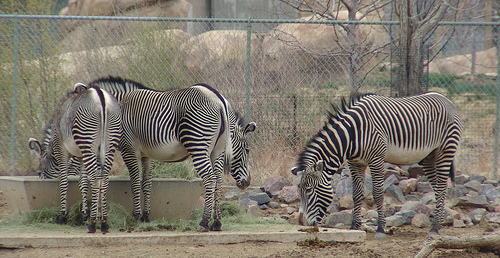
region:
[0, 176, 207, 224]
a trough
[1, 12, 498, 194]
a chain link fence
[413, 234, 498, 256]
a branch off to the side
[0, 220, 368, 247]
a slab of concrete being used as a ground surface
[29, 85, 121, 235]
a zebra eating from a trough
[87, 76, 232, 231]
a zebra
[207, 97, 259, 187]
a zebra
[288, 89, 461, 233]
a zebra eating something off of the ground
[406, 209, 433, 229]
a pinkish rock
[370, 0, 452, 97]
a tree behind the chain link fence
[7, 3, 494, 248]
animals in a zoo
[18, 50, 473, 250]
zebras in front of a fence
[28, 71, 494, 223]
three zebras eating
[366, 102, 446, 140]
zebra stripes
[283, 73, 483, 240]
one zebra eating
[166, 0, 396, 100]
rocks behind a fence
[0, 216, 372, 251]
slab of concrete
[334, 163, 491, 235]
large pile of rocks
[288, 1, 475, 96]
one tree behind a fence, one tree in front of a fence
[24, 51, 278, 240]
three zebras eating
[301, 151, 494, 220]
A pile of rocks behind a zebra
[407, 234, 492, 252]
A log on the ground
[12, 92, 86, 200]
A zebra drinks from a trough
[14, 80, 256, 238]
Three zebras stand together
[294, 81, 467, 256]
One zebra stands alone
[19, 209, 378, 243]
A concrete platform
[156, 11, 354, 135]
A tall chain link fence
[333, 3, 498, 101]
Trees on both sides of the fence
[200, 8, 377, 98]
Roles of hay on the other side of the fence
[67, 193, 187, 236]
Fresh green hay at the zebras' feet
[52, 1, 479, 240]
Zebras standing near each other.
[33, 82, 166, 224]
Zebra is black and white.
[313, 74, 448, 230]
Zebra has stripes.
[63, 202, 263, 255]
Zebra standing on concrete slab.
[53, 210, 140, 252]
Zebra has black feet.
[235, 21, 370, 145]
Tall chain link fence behind zebras.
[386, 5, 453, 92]
Brown tree behind zebra.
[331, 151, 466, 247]
Pile of rocks behind zebra.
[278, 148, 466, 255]
Pile of rocks are gray.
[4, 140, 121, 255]
Zebra eating out of trough.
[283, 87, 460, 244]
a zebra is grazing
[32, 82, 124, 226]
a zebra is grazing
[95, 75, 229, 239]
a zebra is grazing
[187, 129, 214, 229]
a zebra's leg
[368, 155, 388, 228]
a zebra's leg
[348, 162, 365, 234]
a zebra's leg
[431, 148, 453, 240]
a zebra's leg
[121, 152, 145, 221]
a zebra's leg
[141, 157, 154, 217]
a zebra's leg